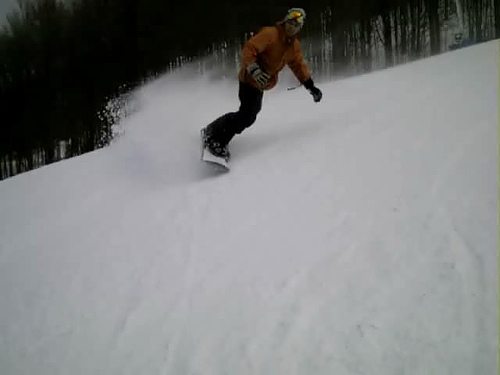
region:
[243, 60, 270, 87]
The person is wearing gloves.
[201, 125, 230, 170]
The person is on a snowboard.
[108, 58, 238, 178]
Snow is flying into the air.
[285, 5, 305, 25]
The snowboarder is wearing a hat.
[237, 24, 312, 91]
The snowboarder wears an orange jacket.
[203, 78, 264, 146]
The snowboarder has dark pants.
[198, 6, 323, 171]
The snowboarder is moving.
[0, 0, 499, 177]
A forest of trees are in the background.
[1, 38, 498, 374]
The snowboarder is on a hill.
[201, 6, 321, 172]
The snowboarder is tilted towards the ground.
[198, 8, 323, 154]
A person on a snowboard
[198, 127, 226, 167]
A snowboard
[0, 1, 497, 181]
A large wooded area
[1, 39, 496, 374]
A large hill covered in snow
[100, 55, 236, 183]
some snow in the air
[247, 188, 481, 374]
some tracks in the snow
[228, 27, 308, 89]
an orange jacket on a snowboarder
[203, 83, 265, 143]
some black pants on a snowboarder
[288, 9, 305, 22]
A pair of goggles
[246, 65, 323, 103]
A pair of grey and black gloves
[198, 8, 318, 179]
man riding on snow board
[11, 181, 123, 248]
white snow on hill side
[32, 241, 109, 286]
white snow on hill side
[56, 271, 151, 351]
white snow on hill side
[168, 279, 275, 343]
white snow on hill side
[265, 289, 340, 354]
white snow on hill side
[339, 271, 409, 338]
white snow on hill side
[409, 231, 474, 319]
white snow on hill side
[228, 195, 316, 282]
white snow on hill side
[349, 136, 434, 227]
white snow on hill side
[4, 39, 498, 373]
snow covered section of hill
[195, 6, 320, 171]
male on a surfboard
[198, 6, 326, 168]
man with yellow goggles on his head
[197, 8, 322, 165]
the man is snowboarding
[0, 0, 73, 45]
darkening sky seen behind the trees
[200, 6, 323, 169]
man falling to the right on a snowboard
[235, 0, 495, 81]
grove of dead trees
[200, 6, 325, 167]
man wearing gloves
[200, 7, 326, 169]
man wearing orange jacket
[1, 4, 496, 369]
winter seaon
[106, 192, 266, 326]
Ground is white color.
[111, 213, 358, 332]
Snow is in ground.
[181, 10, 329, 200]
one man is snowboarding.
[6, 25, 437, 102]
Trees are behind the man.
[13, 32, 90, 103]
Trees are green color.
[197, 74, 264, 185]
Man is wearing black pant.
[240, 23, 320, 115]
Man is wearing red shirt.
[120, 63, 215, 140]
snow is splashing.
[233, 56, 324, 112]
Man is wearing brown gloves.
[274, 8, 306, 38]
Man is wearing brown cap.